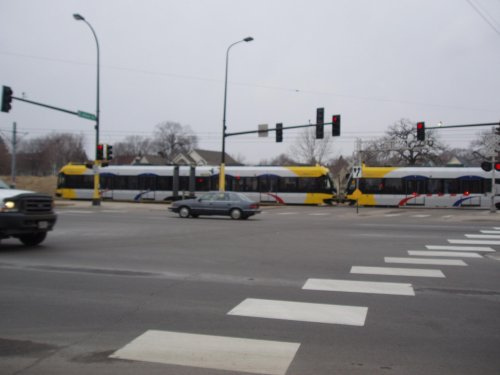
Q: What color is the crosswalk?
A: White.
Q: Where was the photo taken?
A: City Streets.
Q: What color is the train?
A: Yellow and White.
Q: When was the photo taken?
A: Daytime.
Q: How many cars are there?
A: Two.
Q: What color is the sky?
A: Gray.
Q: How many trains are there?
A: One.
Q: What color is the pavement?
A: Dark Gray.